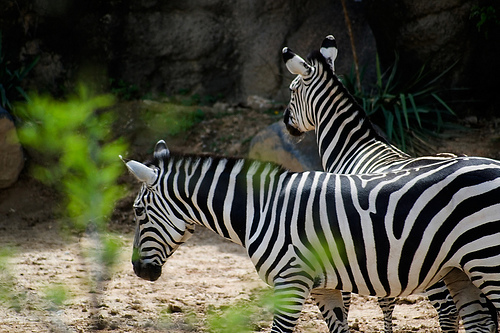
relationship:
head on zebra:
[284, 45, 338, 136] [274, 30, 474, 176]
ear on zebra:
[111, 145, 158, 185] [118, 137, 498, 330]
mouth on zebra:
[132, 255, 164, 284] [118, 137, 498, 330]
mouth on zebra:
[280, 107, 301, 135] [262, 29, 466, 166]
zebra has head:
[283, 34, 498, 330] [280, 50, 334, 135]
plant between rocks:
[354, 62, 459, 144] [36, 10, 492, 119]